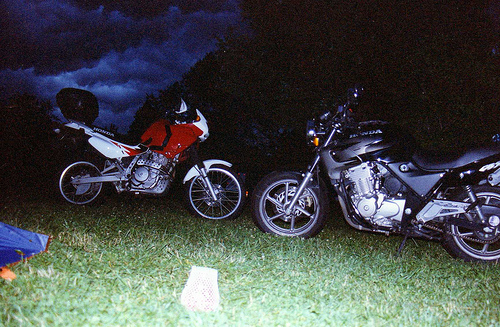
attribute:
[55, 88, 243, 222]
red honda — white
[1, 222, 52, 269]
camping trip — blue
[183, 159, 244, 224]
front wheel — white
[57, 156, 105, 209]
on the rear wheel — aluminum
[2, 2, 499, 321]
photo — nighttime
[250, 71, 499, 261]
both motorcycles — hondas, honda's, street motorcycle, black, grey, honda street bike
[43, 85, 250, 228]
motorcycle — red, white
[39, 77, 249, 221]
motorcycle — white, red